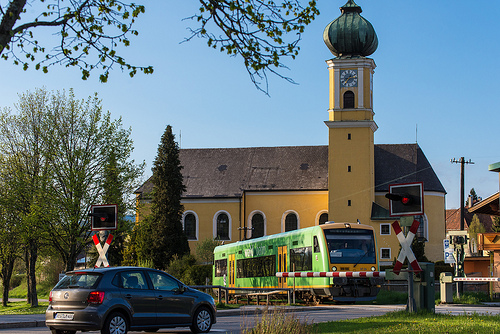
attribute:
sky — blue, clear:
[150, 48, 210, 117]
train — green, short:
[189, 207, 369, 318]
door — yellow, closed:
[215, 242, 301, 301]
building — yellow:
[171, 38, 446, 264]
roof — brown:
[168, 145, 397, 209]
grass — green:
[321, 300, 405, 333]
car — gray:
[43, 260, 198, 331]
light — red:
[378, 184, 416, 228]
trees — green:
[5, 93, 171, 254]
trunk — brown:
[4, 249, 61, 304]